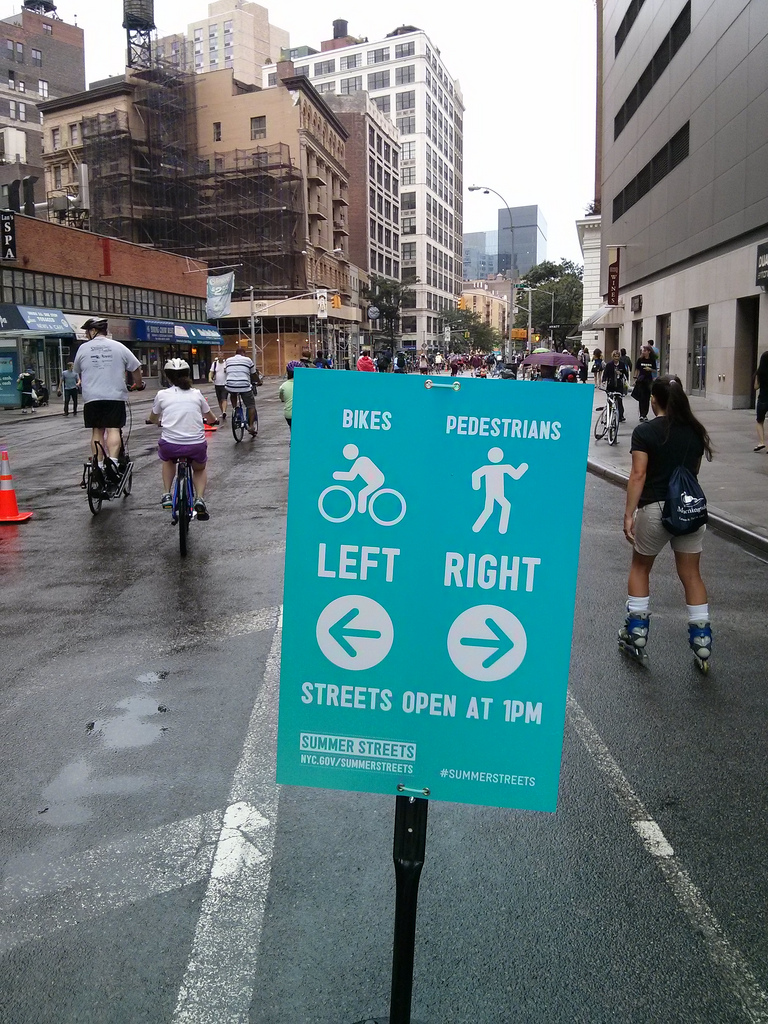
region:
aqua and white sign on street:
[264, 361, 600, 1022]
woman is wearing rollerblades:
[613, 372, 729, 672]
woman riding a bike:
[144, 357, 220, 545]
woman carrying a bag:
[616, 372, 729, 682]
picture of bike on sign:
[272, 369, 600, 814]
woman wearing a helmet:
[147, 359, 220, 555]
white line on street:
[6, 362, 761, 1020]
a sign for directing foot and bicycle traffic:
[274, 366, 595, 811]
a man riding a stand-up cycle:
[65, 315, 143, 516]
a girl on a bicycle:
[147, 354, 218, 553]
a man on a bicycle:
[222, 346, 260, 442]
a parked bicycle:
[592, 391, 622, 449]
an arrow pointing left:
[313, 592, 394, 670]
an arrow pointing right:
[444, 604, 525, 680]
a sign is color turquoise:
[241, 357, 612, 1016]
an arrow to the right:
[446, 600, 528, 684]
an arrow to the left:
[311, 586, 399, 674]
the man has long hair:
[602, 367, 731, 689]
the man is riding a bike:
[219, 336, 265, 452]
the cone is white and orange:
[1, 441, 47, 540]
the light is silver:
[459, 166, 533, 274]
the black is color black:
[368, 777, 436, 1022]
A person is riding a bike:
[143, 357, 212, 552]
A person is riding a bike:
[224, 347, 259, 443]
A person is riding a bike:
[77, 318, 142, 514]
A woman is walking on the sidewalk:
[631, 342, 659, 422]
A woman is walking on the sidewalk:
[603, 347, 626, 425]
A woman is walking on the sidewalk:
[591, 346, 605, 386]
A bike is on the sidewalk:
[592, 386, 627, 444]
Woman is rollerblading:
[617, 373, 711, 674]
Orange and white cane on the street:
[0, 449, 32, 525]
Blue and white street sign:
[273, 365, 596, 812]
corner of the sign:
[512, 340, 649, 463]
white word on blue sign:
[261, 643, 421, 749]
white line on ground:
[562, 769, 725, 964]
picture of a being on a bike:
[270, 419, 434, 540]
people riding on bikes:
[46, 289, 286, 527]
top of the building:
[256, 11, 476, 96]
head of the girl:
[628, 342, 727, 436]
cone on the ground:
[0, 430, 76, 535]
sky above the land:
[487, 25, 564, 147]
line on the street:
[578, 771, 743, 987]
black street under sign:
[523, 849, 651, 999]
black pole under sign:
[296, 782, 481, 1018]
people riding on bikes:
[20, 301, 325, 574]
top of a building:
[239, 25, 483, 138]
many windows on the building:
[365, 75, 482, 288]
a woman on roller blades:
[616, 369, 715, 676]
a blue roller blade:
[611, 610, 650, 662]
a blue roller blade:
[686, 618, 715, 671]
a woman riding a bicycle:
[148, 356, 222, 550]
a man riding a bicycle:
[220, 340, 262, 440]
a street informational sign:
[272, 360, 593, 814]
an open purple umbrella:
[523, 347, 581, 367]